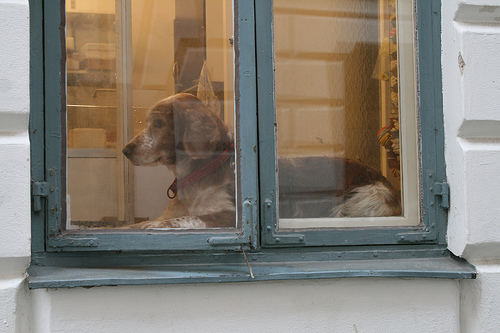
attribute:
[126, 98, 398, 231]
dog — facing, sitting, brown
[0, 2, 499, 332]
house — daytime, lit, white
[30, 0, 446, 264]
frame — blue, grey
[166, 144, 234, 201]
collar — red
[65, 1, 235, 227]
window — reflective, pne, glass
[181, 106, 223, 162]
ear — brown, long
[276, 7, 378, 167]
wall — white, painted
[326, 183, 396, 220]
tail — furry, white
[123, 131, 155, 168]
nose — black, brown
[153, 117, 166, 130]
eye — open, brown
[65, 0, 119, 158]
shelf — full